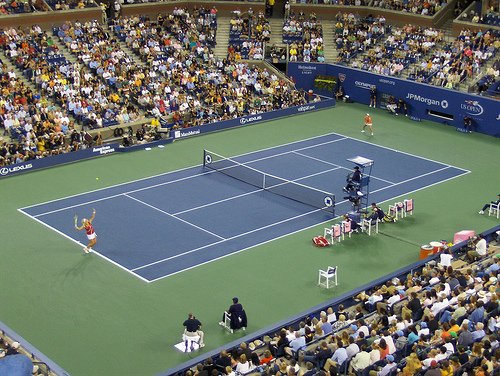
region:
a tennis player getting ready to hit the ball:
[66, 202, 103, 258]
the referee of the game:
[343, 150, 366, 205]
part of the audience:
[225, 270, 499, 367]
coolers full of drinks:
[411, 236, 441, 263]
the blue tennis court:
[18, 126, 470, 313]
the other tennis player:
[357, 112, 377, 132]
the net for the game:
[200, 150, 352, 227]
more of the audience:
[338, 14, 493, 113]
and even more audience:
[7, 25, 304, 136]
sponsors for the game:
[398, 90, 485, 125]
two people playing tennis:
[12, 111, 475, 253]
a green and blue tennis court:
[2, 95, 499, 375]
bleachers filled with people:
[0, 14, 333, 170]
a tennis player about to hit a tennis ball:
[70, 174, 102, 257]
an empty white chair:
[317, 261, 342, 290]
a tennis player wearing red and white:
[359, 111, 377, 136]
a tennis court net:
[202, 145, 339, 222]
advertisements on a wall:
[402, 79, 492, 131]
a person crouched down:
[460, 116, 477, 134]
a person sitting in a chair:
[217, 296, 249, 332]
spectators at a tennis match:
[10, 5, 292, 126]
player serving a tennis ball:
[63, 199, 105, 261]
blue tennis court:
[23, 126, 473, 306]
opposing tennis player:
[351, 107, 381, 139]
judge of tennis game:
[334, 143, 378, 223]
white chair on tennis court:
[312, 258, 349, 290]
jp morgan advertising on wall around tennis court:
[403, 86, 456, 111]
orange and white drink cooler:
[413, 240, 437, 260]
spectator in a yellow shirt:
[287, 38, 299, 61]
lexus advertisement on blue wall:
[6, 162, 41, 177]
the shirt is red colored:
[80, 221, 95, 235]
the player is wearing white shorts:
[86, 231, 96, 239]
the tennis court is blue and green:
[1, 88, 492, 373]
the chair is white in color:
[316, 263, 338, 288]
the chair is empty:
[315, 264, 340, 288]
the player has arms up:
[71, 208, 100, 255]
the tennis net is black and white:
[193, 143, 342, 220]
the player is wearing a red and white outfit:
[357, 111, 378, 140]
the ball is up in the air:
[92, 174, 101, 181]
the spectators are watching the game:
[2, 6, 494, 167]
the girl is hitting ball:
[73, 177, 100, 255]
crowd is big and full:
[3, 35, 499, 370]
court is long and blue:
[18, 132, 470, 284]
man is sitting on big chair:
[340, 155, 371, 219]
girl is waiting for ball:
[360, 110, 375, 135]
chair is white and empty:
[317, 264, 340, 287]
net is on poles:
[202, 147, 337, 217]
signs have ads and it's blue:
[289, 61, 499, 137]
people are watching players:
[2, 35, 499, 374]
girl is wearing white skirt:
[73, 205, 104, 252]